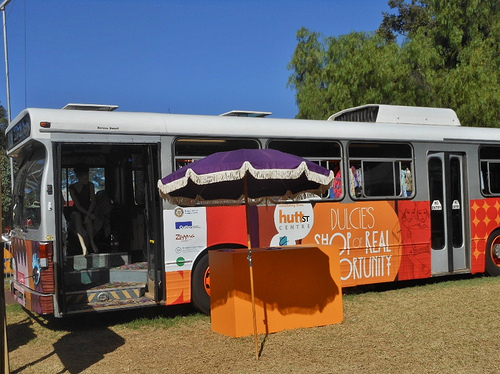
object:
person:
[68, 162, 102, 257]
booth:
[208, 243, 345, 338]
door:
[424, 149, 471, 277]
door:
[54, 138, 165, 312]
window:
[169, 140, 267, 170]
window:
[476, 141, 500, 196]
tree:
[285, 0, 500, 125]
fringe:
[156, 161, 332, 206]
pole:
[241, 185, 260, 361]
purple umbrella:
[157, 148, 334, 359]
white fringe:
[305, 170, 330, 185]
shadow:
[210, 247, 339, 315]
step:
[56, 269, 160, 317]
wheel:
[191, 255, 210, 316]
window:
[9, 155, 50, 232]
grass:
[0, 270, 497, 371]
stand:
[209, 244, 344, 336]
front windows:
[54, 141, 165, 313]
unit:
[327, 103, 459, 130]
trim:
[157, 162, 336, 208]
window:
[424, 156, 468, 249]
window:
[345, 140, 417, 201]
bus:
[0, 102, 499, 320]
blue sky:
[0, 0, 407, 99]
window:
[266, 138, 344, 203]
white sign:
[431, 199, 443, 211]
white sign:
[273, 203, 314, 241]